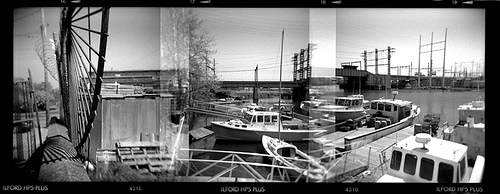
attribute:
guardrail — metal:
[168, 145, 348, 184]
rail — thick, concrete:
[37, 113, 90, 183]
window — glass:
[258, 115, 264, 123]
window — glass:
[264, 113, 271, 123]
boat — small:
[261, 133, 324, 179]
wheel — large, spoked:
[57, 6, 110, 151]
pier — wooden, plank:
[297, 102, 420, 182]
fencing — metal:
[172, 144, 309, 187]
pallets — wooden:
[113, 139, 177, 172]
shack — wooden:
[89, 76, 172, 165]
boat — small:
[261, 134, 334, 184]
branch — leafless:
[191, 32, 213, 57]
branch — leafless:
[162, 43, 177, 63]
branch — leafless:
[194, 27, 209, 57]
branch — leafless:
[185, 15, 203, 30]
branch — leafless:
[195, 52, 214, 63]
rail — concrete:
[39, 112, 98, 185]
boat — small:
[258, 131, 329, 184]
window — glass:
[386, 147, 402, 174]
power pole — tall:
[272, 25, 289, 95]